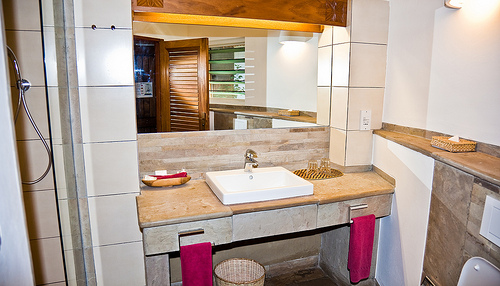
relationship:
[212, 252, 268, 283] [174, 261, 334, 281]
basket on ground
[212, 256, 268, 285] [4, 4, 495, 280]
basket in bathroom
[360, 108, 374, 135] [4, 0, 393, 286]
light switch on wall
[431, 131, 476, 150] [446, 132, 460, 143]
box has tissues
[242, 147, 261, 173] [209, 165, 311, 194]
faucet over bathroom sink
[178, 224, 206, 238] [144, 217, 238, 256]
handle on drawer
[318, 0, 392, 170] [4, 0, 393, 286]
tiles on wall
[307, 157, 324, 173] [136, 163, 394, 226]
glass on countertop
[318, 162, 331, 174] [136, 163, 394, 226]
glass on countertop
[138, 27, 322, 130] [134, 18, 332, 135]
reflections in bathroom mirror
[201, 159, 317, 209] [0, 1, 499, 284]
basin in bathroom